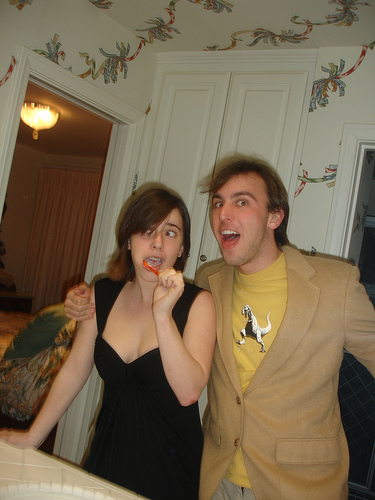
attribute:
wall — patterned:
[290, 47, 374, 256]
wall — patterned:
[0, 0, 158, 114]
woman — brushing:
[0, 180, 216, 498]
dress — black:
[78, 274, 219, 497]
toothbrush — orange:
[140, 258, 158, 279]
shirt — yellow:
[226, 255, 288, 385]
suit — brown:
[188, 250, 371, 497]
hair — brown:
[202, 159, 289, 241]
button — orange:
[233, 436, 244, 447]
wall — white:
[318, 61, 365, 103]